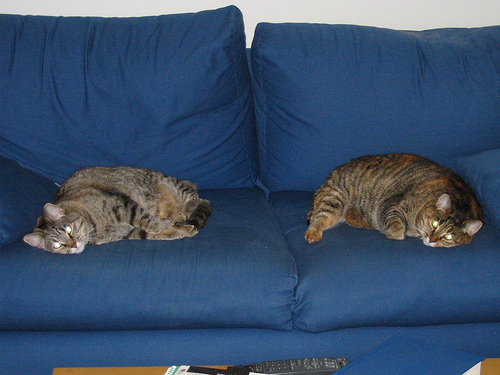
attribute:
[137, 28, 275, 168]
couch — blue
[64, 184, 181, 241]
cat — grey, looking, fat, brown, white, laying, striped, glowing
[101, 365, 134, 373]
table — brown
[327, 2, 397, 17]
wall — white